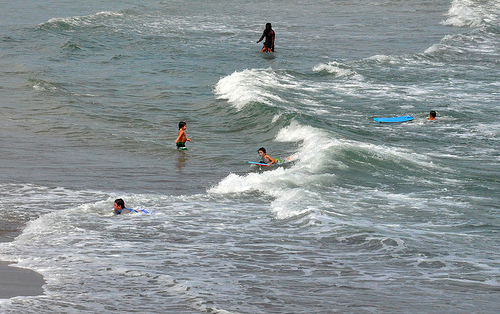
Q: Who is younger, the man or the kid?
A: The kid is younger than the man.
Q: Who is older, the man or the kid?
A: The man is older than the kid.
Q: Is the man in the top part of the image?
A: Yes, the man is in the top of the image.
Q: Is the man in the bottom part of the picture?
A: No, the man is in the top of the image.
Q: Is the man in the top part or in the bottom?
A: The man is in the top of the image.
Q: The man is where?
A: The man is in the water.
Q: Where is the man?
A: The man is in the water.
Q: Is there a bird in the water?
A: No, there is a man in the water.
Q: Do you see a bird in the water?
A: No, there is a man in the water.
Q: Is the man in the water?
A: Yes, the man is in the water.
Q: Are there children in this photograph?
A: Yes, there is a child.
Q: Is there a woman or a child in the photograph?
A: Yes, there is a child.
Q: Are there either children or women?
A: Yes, there is a child.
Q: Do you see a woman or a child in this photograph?
A: Yes, there is a child.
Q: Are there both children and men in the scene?
A: Yes, there are both a child and a man.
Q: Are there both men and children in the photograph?
A: Yes, there are both a child and a man.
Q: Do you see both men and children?
A: Yes, there are both a child and a man.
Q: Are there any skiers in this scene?
A: No, there are no skiers.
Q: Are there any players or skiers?
A: No, there are no skiers or players.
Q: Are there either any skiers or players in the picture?
A: No, there are no skiers or players.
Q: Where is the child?
A: The child is in the water.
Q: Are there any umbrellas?
A: No, there are no umbrellas.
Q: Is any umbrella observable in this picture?
A: No, there are no umbrellas.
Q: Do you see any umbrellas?
A: No, there are no umbrellas.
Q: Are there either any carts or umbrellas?
A: No, there are no umbrellas or carts.